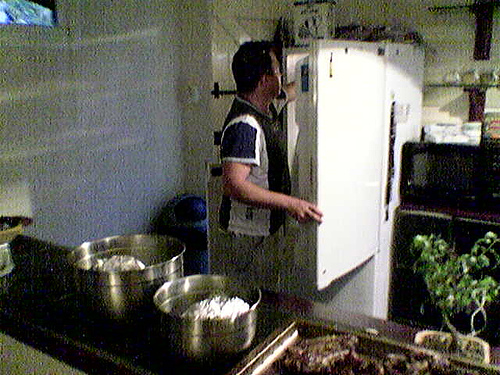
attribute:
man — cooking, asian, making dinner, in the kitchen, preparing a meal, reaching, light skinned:
[218, 38, 298, 290]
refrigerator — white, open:
[282, 38, 424, 318]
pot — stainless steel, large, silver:
[153, 271, 261, 355]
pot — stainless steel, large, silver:
[65, 230, 186, 322]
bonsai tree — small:
[404, 228, 500, 361]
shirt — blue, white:
[217, 98, 296, 237]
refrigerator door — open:
[305, 35, 380, 290]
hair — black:
[229, 40, 273, 102]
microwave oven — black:
[397, 137, 499, 217]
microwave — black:
[399, 136, 499, 212]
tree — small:
[408, 228, 498, 361]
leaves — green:
[422, 236, 497, 308]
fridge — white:
[274, 36, 424, 318]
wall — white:
[2, 2, 186, 219]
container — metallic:
[2, 242, 16, 298]